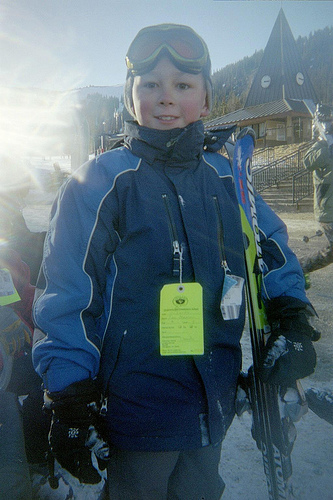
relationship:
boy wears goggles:
[25, 12, 324, 498] [119, 18, 214, 73]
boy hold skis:
[25, 12, 324, 498] [220, 123, 300, 499]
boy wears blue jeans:
[25, 12, 324, 498] [98, 446, 230, 498]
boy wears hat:
[25, 12, 324, 498] [120, 17, 218, 77]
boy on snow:
[25, 12, 324, 498] [228, 428, 261, 498]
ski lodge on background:
[208, 0, 332, 150] [204, 3, 332, 98]